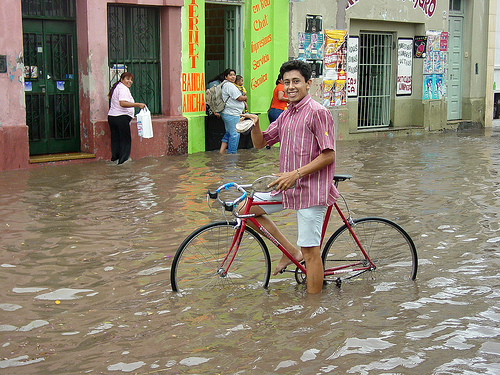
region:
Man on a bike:
[145, 54, 465, 298]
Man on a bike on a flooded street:
[149, 48, 473, 313]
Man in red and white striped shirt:
[241, 48, 359, 336]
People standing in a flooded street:
[74, 26, 260, 178]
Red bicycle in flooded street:
[165, 175, 411, 303]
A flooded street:
[15, 170, 445, 373]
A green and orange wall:
[173, 9, 290, 146]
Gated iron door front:
[342, 25, 410, 138]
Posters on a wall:
[406, 22, 458, 126]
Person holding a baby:
[195, 43, 255, 158]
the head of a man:
[276, 54, 316, 109]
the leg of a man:
[295, 211, 333, 301]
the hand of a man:
[261, 162, 298, 202]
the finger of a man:
[265, 175, 282, 189]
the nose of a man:
[286, 79, 298, 91]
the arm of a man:
[296, 112, 338, 185]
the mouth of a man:
[286, 87, 297, 97]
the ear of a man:
[303, 76, 314, 92]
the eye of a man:
[291, 76, 302, 84]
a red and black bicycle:
[161, 165, 425, 302]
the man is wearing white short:
[175, 140, 490, 341]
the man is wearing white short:
[215, 170, 330, 255]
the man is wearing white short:
[222, 177, 338, 322]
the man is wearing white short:
[235, 173, 428, 290]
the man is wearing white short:
[252, 157, 352, 270]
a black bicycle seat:
[331, 167, 358, 186]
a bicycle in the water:
[163, 172, 429, 299]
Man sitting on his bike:
[248, 62, 373, 304]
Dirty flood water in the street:
[50, 240, 167, 354]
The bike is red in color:
[143, 128, 436, 344]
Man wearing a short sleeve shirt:
[265, 105, 370, 226]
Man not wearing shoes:
[260, 215, 342, 327]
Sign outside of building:
[174, 7, 222, 151]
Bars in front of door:
[355, 30, 397, 140]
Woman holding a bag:
[87, 45, 157, 156]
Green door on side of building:
[22, 16, 87, 157]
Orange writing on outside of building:
[181, 16, 213, 128]